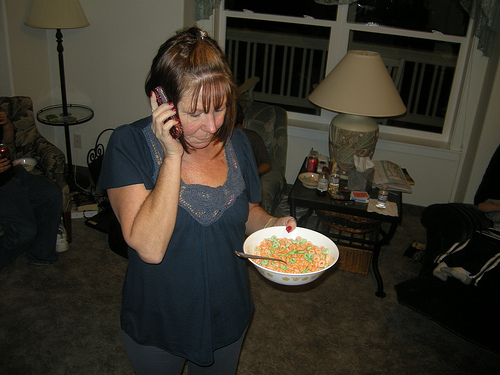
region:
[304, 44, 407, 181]
a large table lamp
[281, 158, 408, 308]
a small black table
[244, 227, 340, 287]
a large white bowl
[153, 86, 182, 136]
a woman's phone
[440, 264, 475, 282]
a boy's white sock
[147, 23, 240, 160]
a woman's brown hair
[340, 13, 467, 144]
part of a window of a home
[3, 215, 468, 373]
dark colored carpet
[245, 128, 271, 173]
the arm of a man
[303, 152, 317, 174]
a red can drink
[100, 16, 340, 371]
A woman talking on the phone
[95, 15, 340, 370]
A woman holding a bowl of cereal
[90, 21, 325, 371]
A woman in a blue shirt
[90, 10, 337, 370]
A woman with red painted nails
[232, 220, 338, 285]
A bowl of 'Apple Jacks' cereal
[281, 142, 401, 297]
A small black table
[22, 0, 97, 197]
A black floor lamp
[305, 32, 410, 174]
A green table lamp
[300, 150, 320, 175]
A red can on a table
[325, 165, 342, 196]
A water bottle on a table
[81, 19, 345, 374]
A woman is in the foreground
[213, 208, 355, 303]
Woman is holding a bowl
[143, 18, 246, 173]
Woman has brown hair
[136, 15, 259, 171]
Woman is looking down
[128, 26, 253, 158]
Woman is on her cell phone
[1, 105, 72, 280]
A person in the background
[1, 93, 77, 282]
Person is sitting down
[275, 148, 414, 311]
A small table in the background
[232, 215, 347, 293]
Bowl is full of cereal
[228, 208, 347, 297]
The cereal is Green, Orange and Pink in color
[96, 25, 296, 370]
woman talking on phone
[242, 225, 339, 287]
round bowl of round cereal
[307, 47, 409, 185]
lamp sitting on a table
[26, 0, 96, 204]
floor lamp by a chair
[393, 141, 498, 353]
brown chair sitting on the carpet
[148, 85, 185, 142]
phone in womans hand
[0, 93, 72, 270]
someone sitting in a chair eating cereal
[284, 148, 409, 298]
wooden stand holding miscellaneous items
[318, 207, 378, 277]
baskets under the table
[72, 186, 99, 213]
book on the floor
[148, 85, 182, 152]
a woman holding a cell phone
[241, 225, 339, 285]
a woman holding a bowl in her hand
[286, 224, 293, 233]
red nail polish on a thumb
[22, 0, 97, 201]
a standing lamp with a white lampshade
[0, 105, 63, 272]
a person sitting on a couch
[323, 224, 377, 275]
a wicker basket under a table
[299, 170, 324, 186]
a bowl on a table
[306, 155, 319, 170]
a red can of soda on a table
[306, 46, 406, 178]
a lamp on a table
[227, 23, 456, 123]
a white wooden fence outside the window